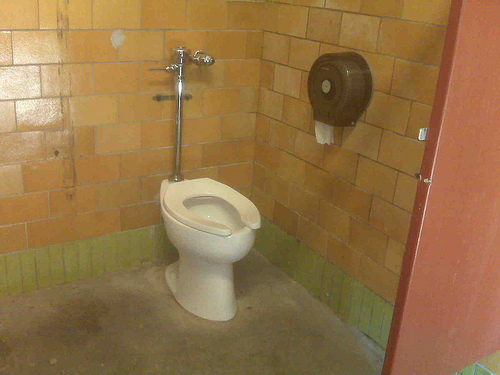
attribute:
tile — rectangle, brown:
[14, 100, 65, 131]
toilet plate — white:
[161, 178, 261, 233]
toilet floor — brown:
[105, 310, 280, 374]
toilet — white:
[153, 47, 262, 327]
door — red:
[415, 42, 482, 359]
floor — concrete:
[17, 230, 367, 371]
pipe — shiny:
[169, 72, 189, 103]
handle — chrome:
[130, 62, 212, 107]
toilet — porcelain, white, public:
[145, 37, 265, 332]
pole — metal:
[160, 64, 202, 184]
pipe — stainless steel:
[151, 57, 208, 179]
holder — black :
[304, 52, 373, 131]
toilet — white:
[160, 173, 262, 322]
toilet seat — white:
[166, 175, 263, 238]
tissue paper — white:
[304, 125, 347, 149]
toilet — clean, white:
[135, 152, 281, 337]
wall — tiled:
[3, 6, 428, 368]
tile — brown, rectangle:
[346, 215, 388, 267]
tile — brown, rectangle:
[354, 155, 399, 203]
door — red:
[367, 2, 499, 368]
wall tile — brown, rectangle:
[91, 60, 142, 96]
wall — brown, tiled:
[2, 0, 148, 262]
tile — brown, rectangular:
[322, 176, 372, 218]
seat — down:
[163, 176, 260, 236]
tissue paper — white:
[313, 115, 340, 152]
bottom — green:
[251, 219, 393, 347]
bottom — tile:
[4, 220, 221, 302]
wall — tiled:
[4, 1, 256, 201]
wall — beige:
[257, 0, 451, 310]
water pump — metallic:
[144, 36, 239, 194]